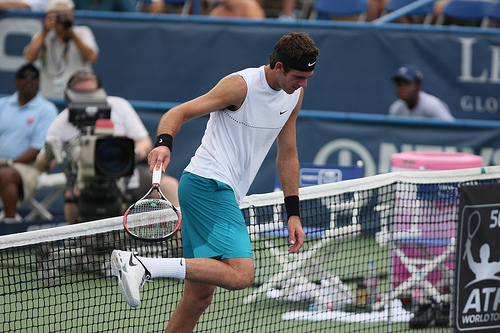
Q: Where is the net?
A: Behind the man.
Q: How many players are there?
A: One.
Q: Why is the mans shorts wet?
A: Sweat.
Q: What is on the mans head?
A: Headband.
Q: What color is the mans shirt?
A: White.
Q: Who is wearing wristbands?
A: The player.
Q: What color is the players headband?
A: Black.